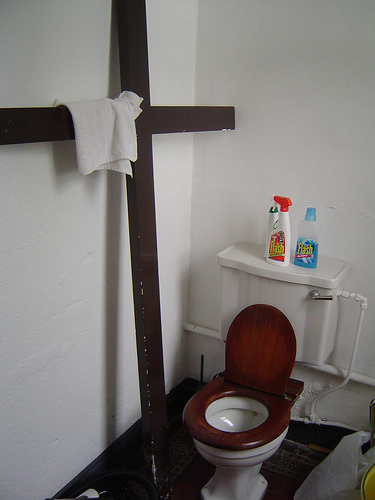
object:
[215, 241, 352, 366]
toilet tank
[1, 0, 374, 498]
bathroom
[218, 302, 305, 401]
bad image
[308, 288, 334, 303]
flusher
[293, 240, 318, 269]
liquid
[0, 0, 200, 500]
wall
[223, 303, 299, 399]
lid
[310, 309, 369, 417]
pipe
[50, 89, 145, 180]
towel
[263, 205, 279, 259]
cleaning product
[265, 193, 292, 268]
cleaning product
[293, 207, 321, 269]
cleaning product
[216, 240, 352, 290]
lid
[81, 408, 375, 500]
ground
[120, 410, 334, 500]
carpet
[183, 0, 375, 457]
walls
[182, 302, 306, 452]
seat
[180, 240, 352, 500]
toilet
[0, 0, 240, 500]
cross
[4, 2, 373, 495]
photo